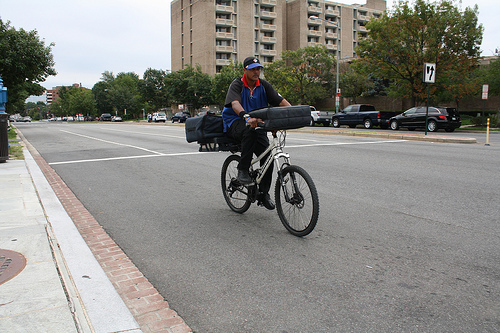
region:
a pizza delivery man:
[182, 20, 342, 233]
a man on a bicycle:
[184, 53, 351, 244]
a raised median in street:
[323, 116, 482, 156]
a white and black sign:
[417, 55, 442, 90]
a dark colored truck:
[324, 95, 396, 135]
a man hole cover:
[0, 242, 34, 296]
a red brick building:
[31, 69, 109, 132]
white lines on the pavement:
[50, 109, 158, 209]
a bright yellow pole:
[482, 110, 491, 152]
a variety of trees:
[61, 61, 201, 117]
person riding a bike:
[195, 43, 333, 230]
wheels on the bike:
[266, 168, 323, 231]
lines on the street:
[119, 128, 172, 185]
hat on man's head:
[238, 46, 273, 76]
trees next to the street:
[98, 66, 164, 127]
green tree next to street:
[361, 8, 481, 99]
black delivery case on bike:
[251, 98, 311, 141]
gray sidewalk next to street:
[48, 232, 96, 297]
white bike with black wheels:
[201, 146, 328, 221]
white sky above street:
[77, 48, 119, 68]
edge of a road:
[93, 247, 142, 294]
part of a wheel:
[287, 157, 317, 226]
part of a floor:
[25, 270, 50, 309]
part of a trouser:
[227, 126, 254, 171]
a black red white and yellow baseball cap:
[245, 55, 264, 70]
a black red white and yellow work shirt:
[222, 75, 288, 145]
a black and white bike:
[217, 125, 322, 237]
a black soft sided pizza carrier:
[247, 105, 314, 133]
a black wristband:
[238, 108, 245, 116]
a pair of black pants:
[228, 120, 275, 190]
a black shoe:
[234, 168, 252, 182]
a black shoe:
[260, 189, 276, 206]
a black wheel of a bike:
[272, 166, 318, 236]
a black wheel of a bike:
[220, 156, 252, 212]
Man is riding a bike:
[181, 38, 362, 260]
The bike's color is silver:
[231, 106, 307, 193]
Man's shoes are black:
[221, 155, 284, 227]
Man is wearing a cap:
[226, 52, 290, 86]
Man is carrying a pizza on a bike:
[221, 56, 321, 149]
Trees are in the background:
[42, 47, 496, 134]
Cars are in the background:
[61, 93, 472, 139]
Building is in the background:
[157, 48, 340, 79]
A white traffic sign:
[416, 56, 445, 140]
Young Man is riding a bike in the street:
[165, 50, 355, 237]